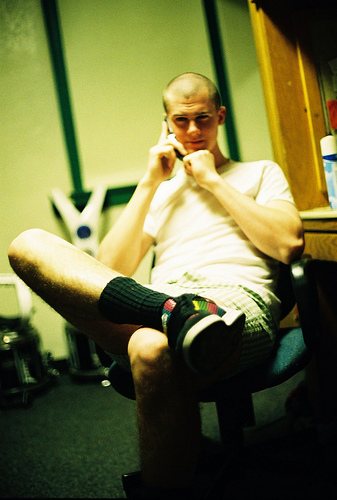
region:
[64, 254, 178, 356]
man wearing black socks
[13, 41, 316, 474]
man talking on a cellular phone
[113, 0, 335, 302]
man sitting at a wooden desk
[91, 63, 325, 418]
man sitting in a blue office chair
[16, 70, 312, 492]
man wearing rainbow colored shoes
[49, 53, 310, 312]
man wearing a white t-shirt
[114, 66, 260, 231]
a man resting his chin on his knuckles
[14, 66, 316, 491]
a man wearing green and white shorts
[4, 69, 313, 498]
a young man talking on a cell phone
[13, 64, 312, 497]
a young man wearing black socks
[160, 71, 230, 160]
the head of a man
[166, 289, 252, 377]
the foot of a man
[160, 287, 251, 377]
the shoe of a man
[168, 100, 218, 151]
the face of a man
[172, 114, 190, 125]
the eye of a man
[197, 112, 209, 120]
the eye of a man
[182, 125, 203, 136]
the nose of a man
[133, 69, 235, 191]
a man talking on a cellphone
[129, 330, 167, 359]
the knee of a man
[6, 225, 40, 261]
the knee of a man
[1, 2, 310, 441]
Man sitting in a chair.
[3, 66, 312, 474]
Man talking on a phone.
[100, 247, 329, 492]
A chair in a room.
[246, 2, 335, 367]
A brown desk.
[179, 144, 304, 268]
The arm of a man.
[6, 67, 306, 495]
A man with his legs crossed.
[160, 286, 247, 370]
Colorful shoes on a man.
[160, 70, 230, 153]
The head of a man.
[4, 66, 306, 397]
Man in a white shirt.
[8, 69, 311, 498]
Man wearing a pair of shorts.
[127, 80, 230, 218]
man is on the phone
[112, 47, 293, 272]
man is on the phone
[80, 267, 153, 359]
the sock is black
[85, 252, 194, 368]
the sock is black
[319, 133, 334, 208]
white and blue aerosol bottle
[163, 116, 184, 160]
flip cell phone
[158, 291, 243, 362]
black shoe with red, green, yellow, and blue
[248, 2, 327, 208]
wood panel on the wall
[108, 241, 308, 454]
green office chair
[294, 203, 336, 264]
part of a wood table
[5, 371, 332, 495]
dark green carpet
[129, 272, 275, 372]
green and white checkered shorts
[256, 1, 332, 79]
shadow in the corner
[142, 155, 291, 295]
white tee shirt